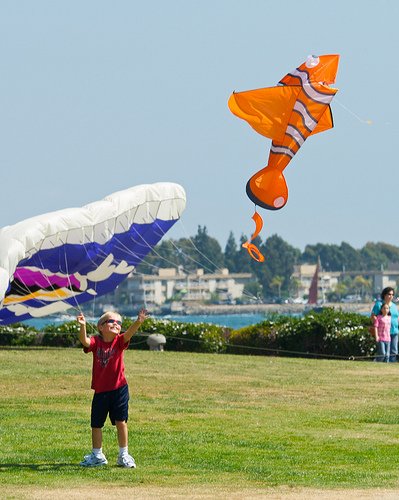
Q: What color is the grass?
A: Green.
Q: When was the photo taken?
A: Daytime.